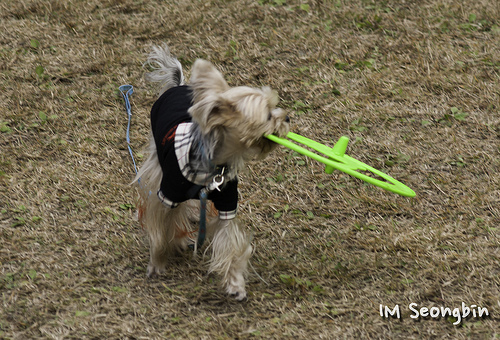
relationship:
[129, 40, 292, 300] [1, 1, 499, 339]
dog in grass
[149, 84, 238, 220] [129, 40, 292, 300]
sweater on dog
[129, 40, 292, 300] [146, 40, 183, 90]
dog has a tail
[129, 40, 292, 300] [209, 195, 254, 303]
dog has a leg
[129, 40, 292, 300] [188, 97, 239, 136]
dog has ears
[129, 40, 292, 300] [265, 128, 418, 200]
dog has toy